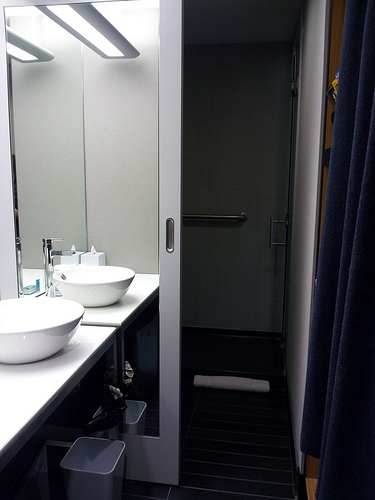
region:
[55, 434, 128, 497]
the trash under the sink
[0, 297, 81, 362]
the sink on the countertop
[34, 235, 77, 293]
the faucet reflection on the wall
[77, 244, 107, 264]
the box of kleenex in the corner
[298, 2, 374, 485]
the blue curtian in the bathroom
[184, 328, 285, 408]
the floor mat on the tile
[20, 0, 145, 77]
the light above the sink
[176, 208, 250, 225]
the rail on the wall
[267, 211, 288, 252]
the handle of the bathroom door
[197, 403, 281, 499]
the floor of the bathroom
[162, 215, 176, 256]
Silver metal handle.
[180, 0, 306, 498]
Stand up shower with white tiles and black floor.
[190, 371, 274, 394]
White rolled up towel.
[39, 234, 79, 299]
Shiny metallic faucet with handle.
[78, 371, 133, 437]
Black plastic unplugged blow dryer.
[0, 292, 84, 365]
Large glass bowl shaped sink.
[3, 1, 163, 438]
Large glass mirror reflecting sink.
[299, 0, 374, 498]
Large blue wrinkled towel.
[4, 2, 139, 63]
Hanging white overhead lamp.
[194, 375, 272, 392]
a towel on the floor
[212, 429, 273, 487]
the floor of the bathroom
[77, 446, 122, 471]
the trashcan is white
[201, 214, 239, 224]
a metal pole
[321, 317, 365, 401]
blue curtains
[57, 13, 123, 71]
a light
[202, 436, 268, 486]
the tile is blue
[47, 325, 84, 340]
a shadow on the bowl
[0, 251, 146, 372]
sink on the counter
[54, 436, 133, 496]
white trash can on the ground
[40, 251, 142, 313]
reflection of the sink in the mirror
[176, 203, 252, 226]
silver handle on the wall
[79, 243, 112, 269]
box of kleenex in the corner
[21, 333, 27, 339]
small light glare on the sink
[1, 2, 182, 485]
mirror on the door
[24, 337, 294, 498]
dark tile on the ground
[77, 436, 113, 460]
shadow on the side of the trash can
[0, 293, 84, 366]
White bowl sink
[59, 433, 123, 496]
Square trash can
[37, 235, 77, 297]
Reflection of bathroom water faucet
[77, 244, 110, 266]
Reflection of white tissue box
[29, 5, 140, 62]
Long rectangular light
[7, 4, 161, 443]
Very tall bathroom mirror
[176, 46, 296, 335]
Shower with safety rail and tile backing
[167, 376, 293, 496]
Dark flooring in the bathroom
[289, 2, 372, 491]
A long, dark blue curtain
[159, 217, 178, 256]
A recessed oval door handle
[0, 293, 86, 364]
sink is color white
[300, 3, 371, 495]
curtain is color blue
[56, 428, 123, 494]
bin is color grey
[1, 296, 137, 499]
bin is under the sink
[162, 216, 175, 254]
door handle is grey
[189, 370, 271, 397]
towel is color white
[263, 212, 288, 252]
door handle is grey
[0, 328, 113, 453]
countertop is white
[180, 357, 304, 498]
floor is color black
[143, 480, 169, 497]
a tile in a floor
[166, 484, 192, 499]
a tile in a floor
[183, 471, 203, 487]
a tile in a floor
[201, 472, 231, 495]
a tile in a floor